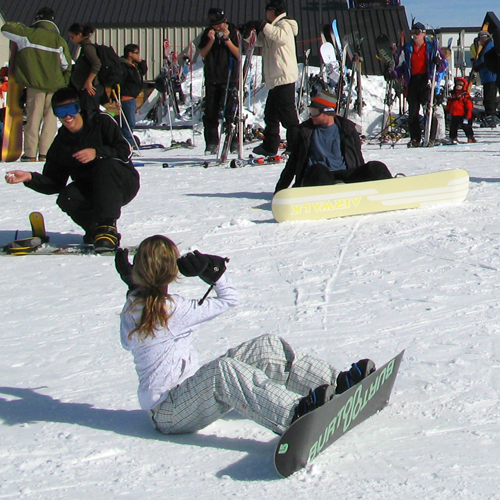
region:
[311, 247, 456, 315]
The snow is white.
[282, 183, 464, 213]
The snowboard is yellow.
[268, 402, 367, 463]
The snowboard is black.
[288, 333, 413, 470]
The snowboard has green writing.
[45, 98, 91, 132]
The man is wearing glasses.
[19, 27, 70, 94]
The man has a green jacket.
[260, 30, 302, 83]
The man has a tan jacket.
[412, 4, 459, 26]
The sky is blue.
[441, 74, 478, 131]
The boy is in red.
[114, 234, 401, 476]
girl on a snowboard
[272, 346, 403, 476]
black and green board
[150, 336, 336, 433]
the pants are plaid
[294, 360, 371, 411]
the boots are black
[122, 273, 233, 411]
the shirt is white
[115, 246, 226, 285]
the gloves are black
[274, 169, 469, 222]
white and yellow board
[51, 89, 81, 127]
head of a man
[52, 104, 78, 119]
the goggles are blue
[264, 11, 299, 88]
the jacket is khaki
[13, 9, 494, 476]
a group of people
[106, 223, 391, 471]
woman sitting on the snow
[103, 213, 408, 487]
woman on a snowboard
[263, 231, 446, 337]
tracks on the snow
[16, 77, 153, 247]
a man kneeling down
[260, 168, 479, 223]
a long yellow snowboard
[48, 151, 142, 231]
black pair of pants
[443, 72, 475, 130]
person wearing a red jacket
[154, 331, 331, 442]
plaid pair of pants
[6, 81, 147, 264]
Man wearing black outdoor snow attire.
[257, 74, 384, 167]
Man wearing striped knit hat.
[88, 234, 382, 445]
Skier wearing white winter clothing.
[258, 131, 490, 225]
Yellow and white snowboard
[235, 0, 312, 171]
Skier wearing white and black coat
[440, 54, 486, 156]
Child wearing red and black coat and black snowpants.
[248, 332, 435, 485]
Black snowboard with green lettering.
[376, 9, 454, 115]
Man wearing red shirt and blue and purple coat.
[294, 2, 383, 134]
Group of snowboards and skiis.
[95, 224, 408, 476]
blond woman in white with snowboard strapped to feet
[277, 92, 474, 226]
man in black coat sitting on snow with snowboard strapped to feet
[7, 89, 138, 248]
crouching smiling man throwing snow at blond woman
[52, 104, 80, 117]
snow goggles worn by snow throwing man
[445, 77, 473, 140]
small child with red and black snow gear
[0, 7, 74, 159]
man with green and white coat and back to camera